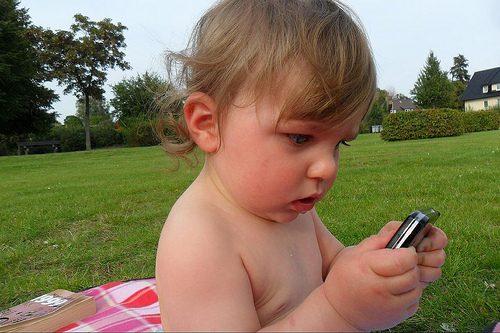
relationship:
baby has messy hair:
[132, 0, 448, 332] [164, 2, 389, 133]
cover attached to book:
[3, 280, 108, 324] [13, 286, 100, 330]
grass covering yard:
[5, 130, 499, 331] [8, 79, 498, 314]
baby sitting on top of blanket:
[132, 0, 448, 332] [19, 281, 182, 324]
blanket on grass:
[53, 277, 164, 332] [5, 130, 499, 331]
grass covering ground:
[17, 122, 498, 326] [17, 134, 477, 330]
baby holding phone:
[132, 0, 448, 332] [379, 190, 445, 266]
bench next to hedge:
[0, 110, 87, 182] [0, 82, 133, 160]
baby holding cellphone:
[132, 0, 448, 332] [344, 182, 446, 264]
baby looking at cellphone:
[132, 0, 448, 332] [357, 191, 486, 302]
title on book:
[0, 278, 98, 319] [1, 245, 121, 330]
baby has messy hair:
[132, 0, 448, 332] [142, 0, 377, 173]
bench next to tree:
[16, 138, 61, 155] [49, 20, 109, 171]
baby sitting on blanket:
[132, 0, 448, 332] [3, 240, 237, 329]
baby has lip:
[153, 0, 443, 330] [257, 178, 347, 213]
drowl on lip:
[295, 201, 314, 214] [257, 178, 347, 213]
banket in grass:
[9, 256, 220, 327] [5, 130, 499, 331]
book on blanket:
[0, 288, 99, 332] [1, 243, 195, 329]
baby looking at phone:
[132, 0, 448, 332] [357, 193, 475, 300]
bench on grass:
[16, 138, 61, 155] [5, 130, 499, 331]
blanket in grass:
[53, 277, 164, 332] [5, 130, 499, 331]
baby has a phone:
[132, 0, 448, 332] [333, 208, 463, 291]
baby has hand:
[132, 0, 448, 332] [297, 183, 472, 311]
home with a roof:
[368, 55, 423, 127] [373, 70, 442, 140]